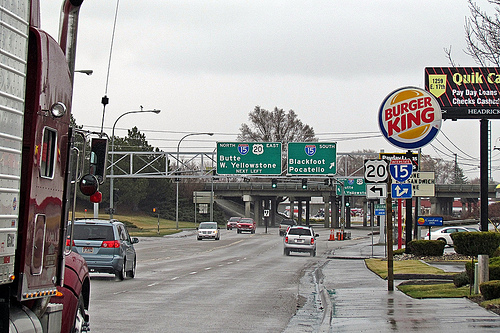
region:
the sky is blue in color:
[279, 26, 355, 62]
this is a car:
[284, 220, 323, 260]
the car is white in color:
[204, 227, 221, 237]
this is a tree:
[246, 107, 308, 139]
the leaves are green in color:
[126, 127, 149, 137]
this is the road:
[173, 264, 246, 307]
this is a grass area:
[141, 205, 166, 235]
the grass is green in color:
[432, 281, 445, 287]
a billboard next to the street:
[424, 63, 498, 125]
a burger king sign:
[376, 90, 441, 151]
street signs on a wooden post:
[363, 158, 420, 293]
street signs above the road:
[216, 140, 335, 175]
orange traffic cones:
[324, 225, 346, 239]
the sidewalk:
[320, 253, 405, 329]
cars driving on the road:
[1, 205, 329, 322]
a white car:
[420, 222, 472, 242]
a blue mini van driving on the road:
[73, 215, 140, 275]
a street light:
[111, 105, 168, 210]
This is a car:
[280, 218, 326, 277]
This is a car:
[188, 216, 222, 247]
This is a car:
[239, 213, 259, 242]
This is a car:
[222, 210, 247, 233]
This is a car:
[416, 217, 471, 254]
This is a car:
[442, 215, 490, 262]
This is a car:
[344, 200, 370, 225]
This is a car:
[279, 214, 333, 269]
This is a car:
[234, 212, 269, 248]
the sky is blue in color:
[323, 8, 372, 87]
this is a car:
[283, 221, 319, 263]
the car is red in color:
[235, 220, 257, 230]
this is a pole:
[381, 172, 416, 283]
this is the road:
[186, 236, 253, 303]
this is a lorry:
[7, 16, 106, 328]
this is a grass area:
[410, 280, 435, 290]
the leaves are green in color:
[120, 126, 142, 138]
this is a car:
[277, 217, 319, 253]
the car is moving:
[283, 222, 317, 255]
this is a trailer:
[0, 141, 71, 266]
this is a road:
[176, 245, 270, 318]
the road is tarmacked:
[144, 239, 265, 330]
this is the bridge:
[167, 148, 214, 178]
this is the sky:
[232, 14, 347, 64]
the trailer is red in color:
[31, 180, 63, 205]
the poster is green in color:
[287, 139, 335, 176]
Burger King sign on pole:
[361, 78, 448, 155]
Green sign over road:
[206, 136, 288, 177]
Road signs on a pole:
[360, 150, 417, 303]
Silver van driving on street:
[54, 206, 158, 294]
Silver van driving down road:
[61, 210, 145, 286]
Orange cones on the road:
[321, 224, 348, 241]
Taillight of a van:
[98, 236, 121, 253]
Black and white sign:
[360, 155, 389, 200]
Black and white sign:
[358, 155, 393, 204]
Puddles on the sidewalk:
[342, 291, 429, 331]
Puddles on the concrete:
[341, 290, 421, 331]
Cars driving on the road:
[61, 201, 376, 329]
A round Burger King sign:
[371, 80, 446, 152]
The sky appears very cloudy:
[35, 0, 495, 186]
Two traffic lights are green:
[261, 170, 311, 195]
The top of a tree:
[227, 100, 324, 150]